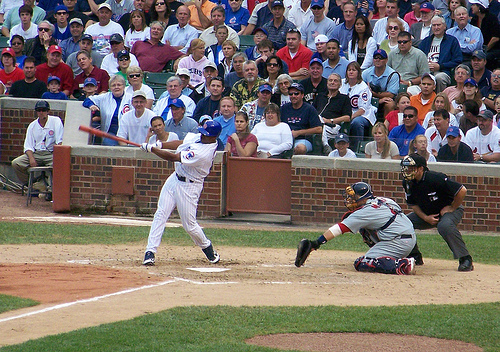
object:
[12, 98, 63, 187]
staff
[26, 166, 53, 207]
stool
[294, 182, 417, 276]
catcher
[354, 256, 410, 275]
guard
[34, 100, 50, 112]
helmet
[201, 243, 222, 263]
shoes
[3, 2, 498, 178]
crowd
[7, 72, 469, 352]
baseball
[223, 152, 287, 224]
gate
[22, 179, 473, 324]
basketball field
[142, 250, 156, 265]
shoes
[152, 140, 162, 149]
baseball glove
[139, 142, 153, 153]
baseball glove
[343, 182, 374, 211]
safety helmet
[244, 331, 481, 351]
circle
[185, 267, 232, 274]
plate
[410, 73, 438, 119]
person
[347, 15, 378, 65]
person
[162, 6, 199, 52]
person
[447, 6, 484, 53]
person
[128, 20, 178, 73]
person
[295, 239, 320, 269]
glove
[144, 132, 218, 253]
uniform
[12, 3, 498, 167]
spectators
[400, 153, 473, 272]
umpire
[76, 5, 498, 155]
box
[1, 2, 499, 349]
stadium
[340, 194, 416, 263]
baseball uniform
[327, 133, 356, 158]
boy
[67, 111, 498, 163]
front row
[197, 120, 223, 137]
helmet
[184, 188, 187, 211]
stripes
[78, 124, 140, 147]
bat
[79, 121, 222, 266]
baseball player